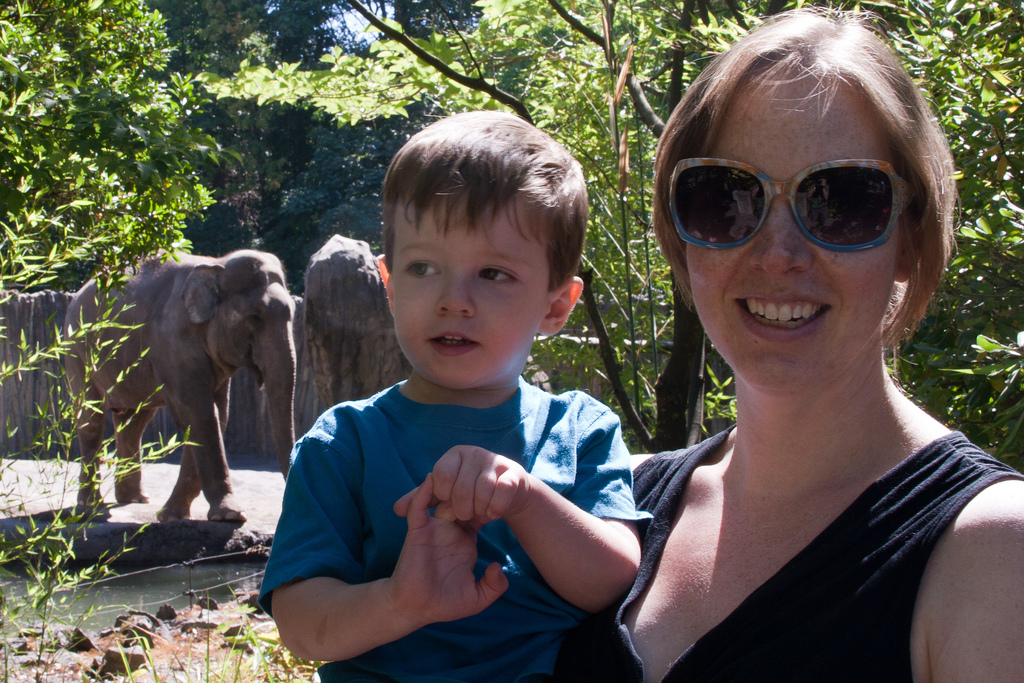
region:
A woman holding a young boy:
[261, 3, 1020, 680]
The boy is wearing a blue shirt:
[261, 85, 654, 677]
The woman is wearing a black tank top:
[596, 10, 1021, 679]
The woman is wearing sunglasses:
[570, 13, 1022, 671]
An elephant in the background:
[52, 236, 297, 530]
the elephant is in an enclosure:
[17, 227, 265, 522]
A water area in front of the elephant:
[0, 541, 275, 622]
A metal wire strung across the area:
[23, 535, 273, 652]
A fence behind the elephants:
[7, 277, 655, 465]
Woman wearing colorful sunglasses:
[620, 0, 1022, 433]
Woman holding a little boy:
[254, 15, 1019, 674]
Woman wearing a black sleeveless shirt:
[608, 0, 1013, 680]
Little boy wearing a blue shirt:
[241, 64, 654, 679]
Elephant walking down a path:
[43, 214, 315, 565]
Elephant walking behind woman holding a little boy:
[61, 21, 967, 660]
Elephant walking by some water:
[5, 202, 353, 675]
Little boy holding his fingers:
[256, 82, 659, 675]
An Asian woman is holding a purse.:
[527, 582, 535, 589]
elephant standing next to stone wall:
[59, 243, 297, 522]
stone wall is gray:
[2, 237, 424, 463]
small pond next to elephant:
[2, 548, 277, 631]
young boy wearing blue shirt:
[258, 108, 645, 679]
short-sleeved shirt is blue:
[257, 379, 643, 680]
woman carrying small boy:
[583, 4, 1020, 679]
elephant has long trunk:
[62, 250, 301, 526]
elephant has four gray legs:
[52, 249, 299, 526]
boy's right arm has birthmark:
[265, 401, 507, 664]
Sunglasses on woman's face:
[654, 156, 912, 255]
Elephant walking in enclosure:
[57, 244, 301, 521]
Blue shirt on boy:
[262, 376, 645, 680]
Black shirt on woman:
[597, 429, 1022, 680]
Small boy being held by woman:
[259, 108, 649, 679]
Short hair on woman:
[645, 19, 956, 343]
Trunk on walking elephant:
[245, 322, 299, 482]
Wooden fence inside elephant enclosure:
[2, 284, 413, 468]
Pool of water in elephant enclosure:
[0, 544, 273, 640]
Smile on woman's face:
[718, 288, 837, 336]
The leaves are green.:
[26, 44, 144, 219]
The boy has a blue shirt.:
[396, 404, 586, 600]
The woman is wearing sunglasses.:
[658, 47, 921, 297]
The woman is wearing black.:
[653, 423, 967, 674]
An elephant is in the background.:
[43, 233, 304, 513]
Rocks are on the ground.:
[68, 584, 182, 673]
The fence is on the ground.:
[2, 288, 85, 456]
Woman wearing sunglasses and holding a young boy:
[258, 14, 1020, 676]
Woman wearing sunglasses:
[588, 11, 1019, 679]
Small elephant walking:
[33, 246, 300, 522]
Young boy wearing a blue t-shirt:
[266, 105, 639, 679]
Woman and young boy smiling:
[263, 7, 1020, 679]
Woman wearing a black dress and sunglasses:
[577, 7, 1020, 679]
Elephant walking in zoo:
[68, 248, 303, 527]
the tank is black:
[584, 366, 995, 677]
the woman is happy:
[572, 29, 972, 669]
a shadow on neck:
[657, 339, 953, 643]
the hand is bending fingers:
[348, 407, 579, 670]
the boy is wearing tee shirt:
[223, 82, 698, 668]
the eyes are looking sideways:
[369, 246, 569, 300]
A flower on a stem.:
[182, 422, 192, 442]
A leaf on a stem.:
[186, 435, 199, 451]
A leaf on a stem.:
[208, 620, 228, 631]